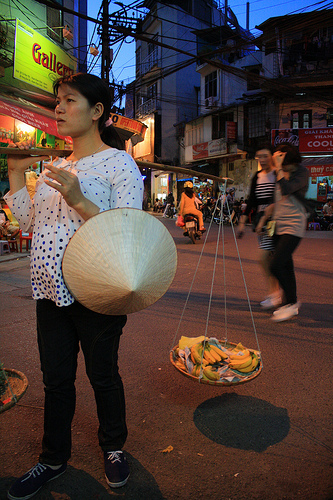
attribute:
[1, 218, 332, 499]
street — city street, busy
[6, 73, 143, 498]
woman — busy, young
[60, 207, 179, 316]
hat — beige, bamboo, conical, straw, woven grass, woven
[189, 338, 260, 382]
bananas — yellow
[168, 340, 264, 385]
tray — wooden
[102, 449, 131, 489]
shoe — black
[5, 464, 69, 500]
shoe — black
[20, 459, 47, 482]
laces — white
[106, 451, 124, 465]
laces — white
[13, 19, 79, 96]
sign — yellow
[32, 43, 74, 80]
writing — red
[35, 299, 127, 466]
pants — black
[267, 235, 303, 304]
pants — black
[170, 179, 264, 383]
chains — white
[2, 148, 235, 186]
pole — wooden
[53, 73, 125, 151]
hair — black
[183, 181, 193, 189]
helmet — yellow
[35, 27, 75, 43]
light — on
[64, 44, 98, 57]
light — on